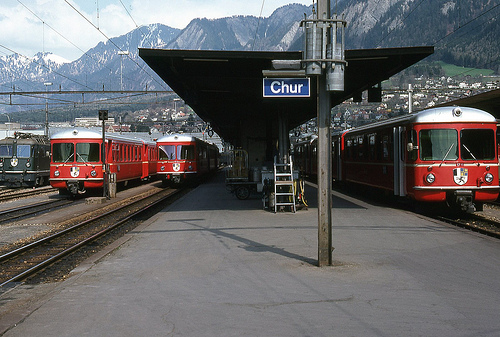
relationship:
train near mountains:
[297, 104, 500, 231] [12, 0, 490, 120]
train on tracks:
[297, 104, 500, 231] [340, 162, 498, 242]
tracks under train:
[340, 162, 498, 242] [297, 104, 500, 231]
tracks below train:
[340, 162, 498, 242] [297, 104, 500, 231]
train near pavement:
[297, 104, 500, 231] [49, 139, 500, 335]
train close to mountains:
[297, 104, 500, 231] [12, 0, 490, 120]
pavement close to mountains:
[49, 139, 500, 335] [12, 0, 490, 120]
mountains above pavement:
[12, 0, 490, 120] [49, 139, 500, 335]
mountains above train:
[12, 0, 490, 120] [297, 104, 500, 231]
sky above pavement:
[4, 1, 450, 75] [49, 139, 500, 335]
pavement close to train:
[49, 139, 500, 335] [297, 104, 500, 231]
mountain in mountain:
[30, 49, 94, 79] [2, 49, 158, 112]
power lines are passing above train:
[34, 51, 134, 111] [66, 128, 190, 218]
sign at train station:
[254, 62, 315, 132] [13, 165, 495, 337]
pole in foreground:
[253, 50, 373, 291] [232, 257, 399, 337]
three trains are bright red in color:
[22, 114, 479, 223] [59, 243, 162, 313]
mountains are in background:
[12, 0, 490, 120] [34, 50, 114, 116]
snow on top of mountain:
[54, 55, 60, 61] [1, 47, 133, 87]